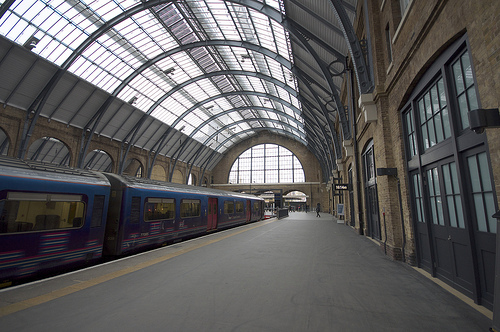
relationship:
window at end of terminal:
[278, 167, 294, 186] [175, 133, 376, 311]